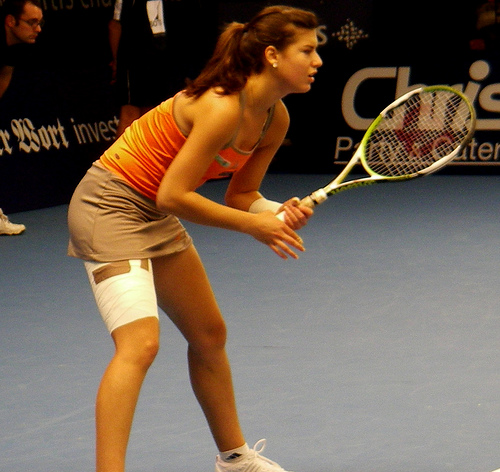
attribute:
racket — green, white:
[313, 80, 483, 225]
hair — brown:
[246, 26, 282, 41]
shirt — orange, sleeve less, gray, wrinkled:
[110, 96, 200, 165]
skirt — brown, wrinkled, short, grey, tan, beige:
[77, 190, 153, 251]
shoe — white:
[216, 460, 288, 471]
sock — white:
[215, 442, 255, 459]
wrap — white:
[94, 262, 162, 334]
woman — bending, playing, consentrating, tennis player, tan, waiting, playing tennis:
[56, 3, 339, 469]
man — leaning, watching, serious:
[3, 3, 46, 244]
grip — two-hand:
[261, 189, 305, 264]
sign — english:
[21, 60, 468, 200]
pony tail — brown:
[149, 16, 266, 128]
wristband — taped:
[256, 198, 282, 216]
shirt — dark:
[3, 39, 24, 79]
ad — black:
[13, 73, 136, 193]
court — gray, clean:
[348, 232, 491, 373]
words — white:
[7, 111, 123, 151]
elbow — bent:
[149, 177, 200, 228]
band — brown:
[241, 19, 252, 32]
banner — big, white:
[325, 65, 497, 183]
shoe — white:
[1, 209, 33, 240]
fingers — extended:
[266, 223, 310, 264]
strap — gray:
[260, 116, 275, 134]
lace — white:
[251, 430, 275, 454]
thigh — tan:
[165, 271, 212, 317]